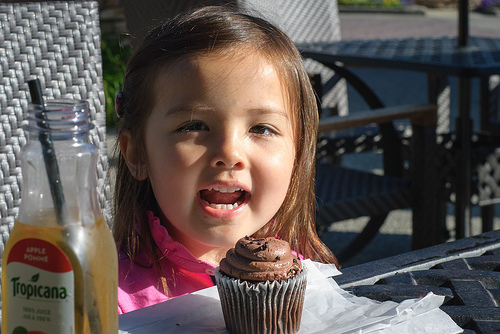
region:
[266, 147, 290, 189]
part of a cheek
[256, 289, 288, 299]
edge of a cake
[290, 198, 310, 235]
hair of a girl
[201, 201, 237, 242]
lip of a girl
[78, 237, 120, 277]
edge of a bottle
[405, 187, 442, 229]
part of a stand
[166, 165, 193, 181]
part of a cheek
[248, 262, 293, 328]
part of a cake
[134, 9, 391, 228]
girl has brown hair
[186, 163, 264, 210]
girl has small teeth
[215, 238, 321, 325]
cupcake in wrapper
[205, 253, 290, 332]
paper wrapper is white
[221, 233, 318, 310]
brown frosting on cupcake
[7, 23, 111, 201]
white chair behind young girl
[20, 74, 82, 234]
black straw in apple juice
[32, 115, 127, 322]
juice in clear bottle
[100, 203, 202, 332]
girl wears pink shirt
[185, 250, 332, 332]
cupcake on black table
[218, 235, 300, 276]
swirled chocolate frosting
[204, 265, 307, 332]
a chocolate cupcake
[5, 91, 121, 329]
a bottle of apple juice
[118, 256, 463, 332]
a white napkin on a table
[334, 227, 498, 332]
a black table top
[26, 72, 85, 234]
a black straw in a bottle of juice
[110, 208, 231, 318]
a pink shirt on a girl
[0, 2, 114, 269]
a white chair behind a girl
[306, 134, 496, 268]
a concrete patio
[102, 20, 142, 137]
grass alongside a patio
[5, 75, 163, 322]
bottle of juice on table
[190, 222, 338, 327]
cupcake made of chocolate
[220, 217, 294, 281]
chocolate sprinkles on cupcake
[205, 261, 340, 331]
cupcake wrapper is white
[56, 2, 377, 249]
girl's hair is brown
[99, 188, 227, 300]
girl's jacket is pink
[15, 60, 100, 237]
straw inside of bottle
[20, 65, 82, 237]
the straw is black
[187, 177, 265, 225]
girl's mouth is open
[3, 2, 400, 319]
girl is sitting in chair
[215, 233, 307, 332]
a chocolate cupcake on the table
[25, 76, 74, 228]
a black straw in the bottle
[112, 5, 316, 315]
a little girl eating a chocolate cupcake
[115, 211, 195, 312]
the little girl is wearing a pink blouse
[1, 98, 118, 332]
a bottle of Tropicana apple juice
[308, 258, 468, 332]
open napkins on the table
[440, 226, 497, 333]
a table with a weaved design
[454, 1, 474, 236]
a shade umbrella pole through the table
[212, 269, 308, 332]
the cupcake wax paper wraper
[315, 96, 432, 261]
a chair with a weaved design